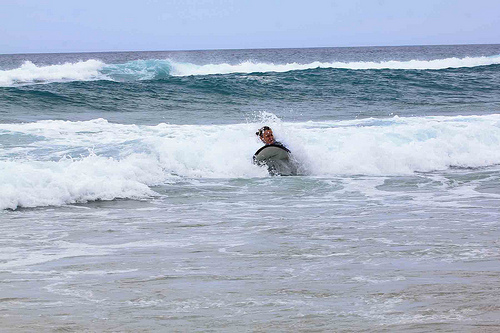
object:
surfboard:
[253, 141, 298, 176]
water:
[0, 45, 469, 114]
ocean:
[1, 42, 499, 331]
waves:
[1, 163, 61, 206]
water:
[320, 186, 496, 324]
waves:
[293, 54, 329, 76]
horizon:
[0, 38, 498, 51]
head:
[255, 125, 276, 144]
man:
[242, 107, 289, 147]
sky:
[2, 6, 498, 38]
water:
[201, 248, 375, 329]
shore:
[6, 22, 498, 330]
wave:
[74, 38, 226, 106]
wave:
[28, 107, 439, 172]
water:
[57, 120, 276, 240]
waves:
[356, 132, 469, 190]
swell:
[20, 63, 496, 141]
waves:
[469, 100, 494, 152]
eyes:
[263, 134, 271, 138]